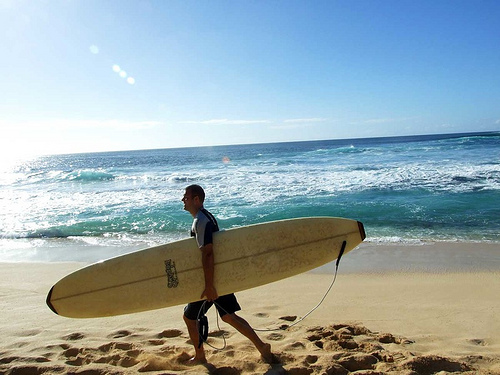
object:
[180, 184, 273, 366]
man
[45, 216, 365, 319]
surfboard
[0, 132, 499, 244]
ocean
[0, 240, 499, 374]
beach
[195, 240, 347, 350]
rope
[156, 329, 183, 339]
footprint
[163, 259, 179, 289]
logo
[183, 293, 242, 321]
shorts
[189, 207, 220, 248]
shirt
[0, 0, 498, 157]
sky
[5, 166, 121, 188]
wave